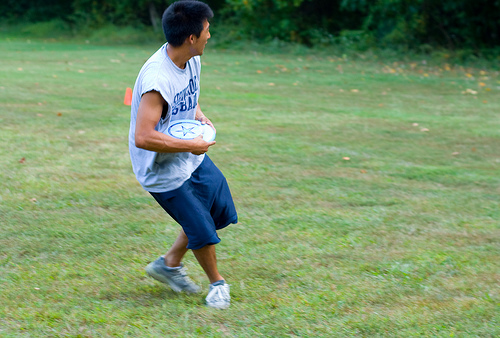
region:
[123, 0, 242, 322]
Person holding a frisbee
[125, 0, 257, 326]
Person wearing blue shorts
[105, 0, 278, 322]
Person wearing a grey shirt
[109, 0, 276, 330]
Person with black hair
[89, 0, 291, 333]
Person wearing shoes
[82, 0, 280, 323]
Person holding a frisbee and wearing shoes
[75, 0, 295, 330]
Person standing in the grass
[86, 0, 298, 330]
Person with brown skin and black hair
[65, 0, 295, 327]
Person with blue shorts holding a frisbee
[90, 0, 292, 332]
Person getting ready to throw a frisbee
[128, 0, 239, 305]
Man holding a Frisbee.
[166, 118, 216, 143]
Frisbee in man's hands.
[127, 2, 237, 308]
Man playing a game of Frisbee.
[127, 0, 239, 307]
Man catching a Frisbee.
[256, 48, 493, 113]
Brown leaves on the ground.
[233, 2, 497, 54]
Bushes on the edge of the field.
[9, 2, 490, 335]
Man playing Frisbee in the park.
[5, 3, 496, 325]
Man holding a Frisbee on the field.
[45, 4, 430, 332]
Man running with Frisbee in hands.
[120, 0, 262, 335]
Man in a running position.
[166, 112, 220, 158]
Guy is holding a Frisbee.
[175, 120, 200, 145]
There is a star on the Frisbee.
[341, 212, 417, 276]
The grass is green.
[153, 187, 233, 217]
The shorts are dark blue.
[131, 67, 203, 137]
The shirt is white.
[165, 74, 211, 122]
Blue writing on the shirt.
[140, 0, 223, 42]
The man has dark hair.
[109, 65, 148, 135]
Orange flag behind the man.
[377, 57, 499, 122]
Leaves on the ground.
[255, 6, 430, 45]
The trees are green.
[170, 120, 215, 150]
this is a frisbey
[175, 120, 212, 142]
the frisbey is white in color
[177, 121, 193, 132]
the frisbey has a star on top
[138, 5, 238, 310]
this is a man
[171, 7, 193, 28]
the man's hair is black in color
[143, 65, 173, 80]
this is a vest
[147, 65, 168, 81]
the vest is grey in color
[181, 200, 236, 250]
the man's knees are bent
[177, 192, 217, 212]
this is a pair of shorts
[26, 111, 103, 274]
the grass is green in color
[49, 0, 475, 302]
a popular summer activity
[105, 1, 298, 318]
a guy playing frisbee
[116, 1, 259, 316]
a man in athletic clothing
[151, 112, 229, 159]
a star on a frisbee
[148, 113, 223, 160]
a blue and white frisbee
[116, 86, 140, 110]
a small orange cone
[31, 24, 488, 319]
a healthy green field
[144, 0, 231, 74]
a man with black hair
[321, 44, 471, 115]
a few dead leaves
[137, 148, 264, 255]
a pair of blue shorts